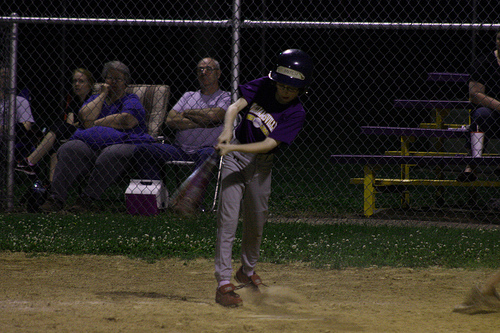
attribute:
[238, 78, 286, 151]
boy — batter, young, playing, player, swinging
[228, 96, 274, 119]
shirt — blue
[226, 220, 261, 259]
pants — gray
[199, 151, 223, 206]
bat — black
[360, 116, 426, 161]
bleachers — purple, yellow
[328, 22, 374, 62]
fence — chain link, tall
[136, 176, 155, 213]
cooler — purple, red, small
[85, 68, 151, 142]
woman — older, sitting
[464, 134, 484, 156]
cup — tall, white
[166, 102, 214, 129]
arms — crossed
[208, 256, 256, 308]
shoes — red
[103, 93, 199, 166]
people — sitting, watching